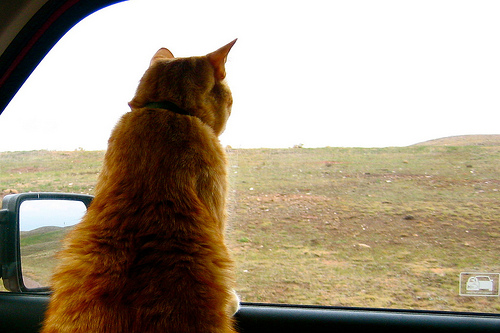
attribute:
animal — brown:
[133, 88, 182, 116]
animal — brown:
[79, 30, 241, 318]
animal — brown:
[57, 26, 307, 331]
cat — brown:
[113, 149, 192, 277]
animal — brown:
[394, 152, 418, 169]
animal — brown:
[110, 31, 230, 328]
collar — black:
[131, 97, 194, 118]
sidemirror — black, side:
[2, 195, 39, 308]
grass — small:
[250, 158, 499, 213]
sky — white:
[3, 1, 499, 146]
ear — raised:
[209, 35, 241, 80]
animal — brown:
[40, 36, 241, 331]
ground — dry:
[1, 133, 498, 313]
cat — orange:
[96, 167, 206, 303]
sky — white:
[398, 49, 446, 97]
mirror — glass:
[6, 188, 100, 298]